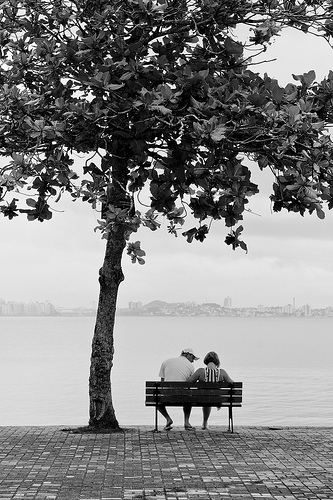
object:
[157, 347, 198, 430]
man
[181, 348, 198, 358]
cap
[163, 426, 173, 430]
flip flops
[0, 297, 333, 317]
city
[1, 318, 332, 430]
water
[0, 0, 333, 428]
tree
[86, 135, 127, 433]
trunk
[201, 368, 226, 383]
shirt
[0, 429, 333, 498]
walkway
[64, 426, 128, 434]
dirt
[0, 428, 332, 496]
cobblestone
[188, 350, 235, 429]
woman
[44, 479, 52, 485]
tile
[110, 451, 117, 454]
tile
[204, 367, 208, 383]
lines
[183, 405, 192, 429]
legs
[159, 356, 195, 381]
shirt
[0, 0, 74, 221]
leaves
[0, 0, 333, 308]
sky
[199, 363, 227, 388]
tank top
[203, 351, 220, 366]
hair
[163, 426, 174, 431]
sandals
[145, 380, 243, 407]
wood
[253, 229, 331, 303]
clouds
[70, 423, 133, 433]
hole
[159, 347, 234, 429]
couple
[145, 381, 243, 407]
bench